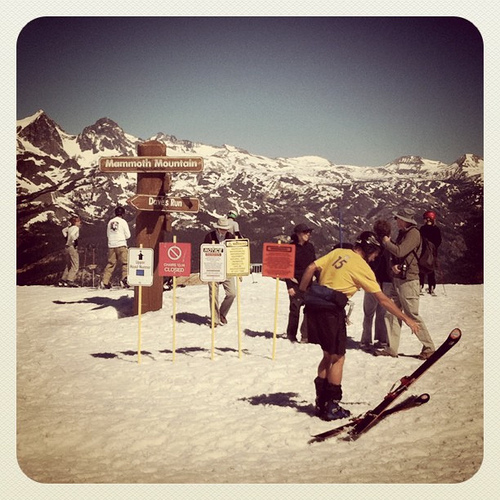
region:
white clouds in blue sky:
[295, 32, 333, 53]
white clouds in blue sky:
[295, 43, 343, 98]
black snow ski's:
[301, 325, 473, 457]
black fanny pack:
[299, 275, 351, 313]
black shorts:
[296, 298, 354, 360]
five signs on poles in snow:
[111, 227, 301, 382]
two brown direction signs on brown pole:
[92, 136, 207, 318]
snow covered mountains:
[20, 101, 489, 308]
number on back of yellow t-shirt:
[330, 249, 351, 279]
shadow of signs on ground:
[79, 328, 275, 374]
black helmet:
[350, 223, 387, 260]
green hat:
[386, 200, 423, 230]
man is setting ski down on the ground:
[365, 213, 454, 385]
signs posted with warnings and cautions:
[133, 230, 285, 288]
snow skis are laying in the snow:
[332, 386, 457, 450]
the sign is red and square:
[151, 236, 196, 292]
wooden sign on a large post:
[99, 147, 204, 213]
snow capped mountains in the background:
[86, 108, 452, 223]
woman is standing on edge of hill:
[56, 211, 84, 294]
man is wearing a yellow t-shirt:
[323, 235, 351, 292]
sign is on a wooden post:
[131, 287, 153, 332]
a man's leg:
[328, 351, 351, 420]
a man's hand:
[373, 295, 423, 337]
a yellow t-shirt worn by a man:
[314, 245, 378, 301]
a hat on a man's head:
[388, 203, 420, 225]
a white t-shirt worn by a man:
[106, 215, 133, 249]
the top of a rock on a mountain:
[30, 105, 47, 123]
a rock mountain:
[23, 109, 495, 264]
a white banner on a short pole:
[123, 246, 155, 351]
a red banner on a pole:
[263, 238, 297, 365]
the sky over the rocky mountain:
[172, 83, 426, 138]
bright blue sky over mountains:
[27, 22, 478, 175]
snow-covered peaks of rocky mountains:
[20, 101, 475, 271]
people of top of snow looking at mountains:
[47, 201, 127, 301]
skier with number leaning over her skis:
[286, 227, 461, 448]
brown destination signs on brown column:
[91, 140, 201, 312]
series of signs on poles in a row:
[120, 221, 296, 361]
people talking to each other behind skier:
[285, 200, 426, 350]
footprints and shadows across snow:
[31, 281, 466, 463]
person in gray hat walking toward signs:
[205, 210, 240, 330]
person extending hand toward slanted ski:
[305, 285, 458, 446]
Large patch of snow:
[98, 381, 213, 473]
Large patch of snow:
[36, 311, 93, 410]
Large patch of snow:
[154, 399, 234, 463]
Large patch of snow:
[23, 337, 78, 403]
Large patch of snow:
[129, 396, 215, 470]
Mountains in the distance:
[218, 131, 481, 189]